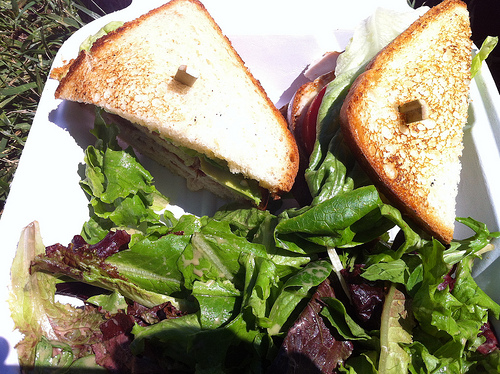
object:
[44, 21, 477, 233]
food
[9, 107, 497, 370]
lettuce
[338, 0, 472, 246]
bread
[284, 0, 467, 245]
bread slices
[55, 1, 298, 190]
bread slices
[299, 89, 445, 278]
lettuce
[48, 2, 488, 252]
bread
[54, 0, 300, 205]
sandwich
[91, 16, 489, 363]
meal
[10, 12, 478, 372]
dish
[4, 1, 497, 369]
plate